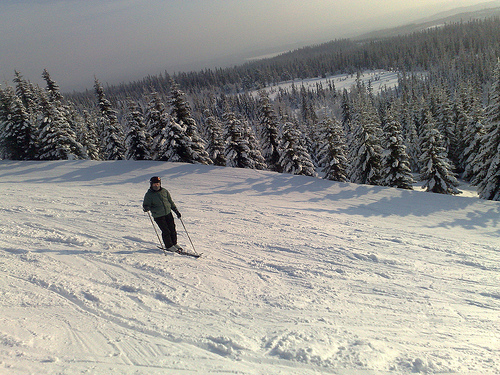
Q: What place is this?
A: It is a field.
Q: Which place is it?
A: It is a field.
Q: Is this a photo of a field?
A: Yes, it is showing a field.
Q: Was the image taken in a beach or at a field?
A: It was taken at a field.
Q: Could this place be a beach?
A: No, it is a field.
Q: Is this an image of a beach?
A: No, the picture is showing a field.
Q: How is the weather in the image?
A: It is cloudy.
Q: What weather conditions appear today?
A: It is cloudy.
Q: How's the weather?
A: It is cloudy.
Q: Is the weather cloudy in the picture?
A: Yes, it is cloudy.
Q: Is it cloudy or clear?
A: It is cloudy.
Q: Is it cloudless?
A: No, it is cloudy.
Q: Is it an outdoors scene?
A: Yes, it is outdoors.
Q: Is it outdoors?
A: Yes, it is outdoors.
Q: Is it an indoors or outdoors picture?
A: It is outdoors.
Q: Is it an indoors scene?
A: No, it is outdoors.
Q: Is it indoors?
A: No, it is outdoors.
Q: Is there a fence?
A: No, there are no fences.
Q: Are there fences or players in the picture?
A: No, there are no fences or players.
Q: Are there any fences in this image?
A: No, there are no fences.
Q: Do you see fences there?
A: No, there are no fences.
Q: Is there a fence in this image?
A: No, there are no fences.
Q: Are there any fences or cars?
A: No, there are no fences or cars.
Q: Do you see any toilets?
A: No, there are no toilets.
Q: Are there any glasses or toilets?
A: No, there are no toilets or glasses.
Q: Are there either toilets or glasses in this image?
A: No, there are no toilets or glasses.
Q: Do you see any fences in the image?
A: No, there are no fences.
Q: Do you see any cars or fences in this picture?
A: No, there are no fences or cars.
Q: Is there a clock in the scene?
A: No, there are no clocks.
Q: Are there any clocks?
A: No, there are no clocks.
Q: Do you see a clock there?
A: No, there are no clocks.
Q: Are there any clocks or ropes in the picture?
A: No, there are no clocks or ropes.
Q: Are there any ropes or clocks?
A: No, there are no clocks or ropes.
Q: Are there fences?
A: No, there are no fences.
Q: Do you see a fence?
A: No, there are no fences.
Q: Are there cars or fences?
A: No, there are no fences or cars.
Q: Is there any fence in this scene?
A: No, there are no fences.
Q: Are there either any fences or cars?
A: No, there are no fences or cars.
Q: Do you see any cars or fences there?
A: No, there are no fences or cars.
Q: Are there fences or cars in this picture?
A: No, there are no cars or fences.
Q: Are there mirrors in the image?
A: No, there are no mirrors.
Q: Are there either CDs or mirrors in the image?
A: No, there are no mirrors or cds.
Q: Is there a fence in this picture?
A: No, there are no fences.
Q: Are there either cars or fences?
A: No, there are no fences or cars.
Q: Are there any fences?
A: No, there are no fences.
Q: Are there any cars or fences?
A: No, there are no fences or cars.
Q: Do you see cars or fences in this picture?
A: No, there are no fences or cars.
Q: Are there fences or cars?
A: No, there are no fences or cars.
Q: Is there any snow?
A: Yes, there is snow.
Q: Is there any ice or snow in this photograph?
A: Yes, there is snow.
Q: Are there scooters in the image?
A: No, there are no scooters.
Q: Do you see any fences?
A: No, there are no fences.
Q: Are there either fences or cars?
A: No, there are no fences or cars.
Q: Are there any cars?
A: No, there are no cars.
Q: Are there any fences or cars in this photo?
A: No, there are no cars or fences.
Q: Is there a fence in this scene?
A: No, there are no fences.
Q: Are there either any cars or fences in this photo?
A: No, there are no fences or cars.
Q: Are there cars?
A: No, there are no cars.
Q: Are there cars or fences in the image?
A: No, there are no cars or fences.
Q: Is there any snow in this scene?
A: Yes, there is snow.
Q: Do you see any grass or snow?
A: Yes, there is snow.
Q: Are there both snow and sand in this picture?
A: No, there is snow but no sand.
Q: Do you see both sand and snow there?
A: No, there is snow but no sand.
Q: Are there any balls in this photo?
A: No, there are no balls.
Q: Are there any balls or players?
A: No, there are no balls or players.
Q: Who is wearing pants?
A: The athlete is wearing pants.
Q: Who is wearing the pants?
A: The athlete is wearing pants.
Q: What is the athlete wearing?
A: The athlete is wearing trousers.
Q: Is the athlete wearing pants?
A: Yes, the athlete is wearing pants.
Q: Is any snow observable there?
A: Yes, there is snow.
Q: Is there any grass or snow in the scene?
A: Yes, there is snow.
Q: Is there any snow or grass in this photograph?
A: Yes, there is snow.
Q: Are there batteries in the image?
A: No, there are no batteries.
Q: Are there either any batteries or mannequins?
A: No, there are no batteries or mannequins.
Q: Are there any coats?
A: Yes, there is a coat.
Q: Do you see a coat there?
A: Yes, there is a coat.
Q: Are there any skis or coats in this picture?
A: Yes, there is a coat.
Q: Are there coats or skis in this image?
A: Yes, there is a coat.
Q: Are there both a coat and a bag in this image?
A: No, there is a coat but no bags.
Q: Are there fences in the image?
A: No, there are no fences.